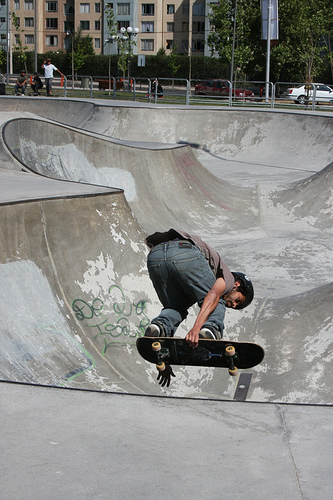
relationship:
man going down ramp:
[143, 225, 255, 340] [0, 382, 332, 500]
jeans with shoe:
[148, 240, 229, 339] [143, 325, 162, 339]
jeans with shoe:
[148, 240, 229, 339] [200, 325, 218, 341]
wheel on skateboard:
[153, 342, 163, 352] [134, 336, 264, 368]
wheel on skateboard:
[226, 345, 236, 357] [134, 336, 264, 368]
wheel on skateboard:
[157, 361, 167, 372] [134, 336, 264, 368]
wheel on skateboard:
[228, 363, 240, 377] [134, 336, 264, 368]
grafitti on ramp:
[72, 286, 151, 352] [0, 111, 250, 400]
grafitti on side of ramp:
[72, 286, 151, 352] [0, 111, 250, 400]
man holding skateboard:
[143, 225, 255, 340] [134, 336, 264, 368]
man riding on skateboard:
[143, 225, 255, 340] [134, 336, 264, 368]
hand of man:
[188, 332, 200, 350] [146, 233, 255, 340]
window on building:
[142, 3, 156, 15] [2, 1, 223, 57]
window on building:
[141, 21, 155, 35] [2, 1, 223, 57]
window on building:
[139, 38, 155, 52] [2, 1, 223, 57]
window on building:
[118, 21, 130, 29] [2, 1, 223, 57]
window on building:
[120, 4, 132, 16] [2, 1, 223, 57]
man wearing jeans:
[146, 233, 255, 340] [148, 240, 229, 339]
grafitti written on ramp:
[72, 286, 151, 352] [0, 111, 250, 400]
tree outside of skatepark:
[278, 1, 332, 88] [1, 94, 332, 478]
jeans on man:
[148, 240, 229, 339] [146, 233, 255, 340]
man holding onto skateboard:
[146, 233, 255, 340] [134, 336, 264, 368]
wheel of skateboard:
[226, 345, 236, 357] [134, 336, 264, 368]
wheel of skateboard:
[228, 363, 240, 377] [134, 336, 264, 368]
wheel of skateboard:
[153, 342, 163, 352] [134, 336, 264, 368]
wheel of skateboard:
[157, 361, 167, 372] [134, 336, 264, 368]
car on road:
[197, 78, 258, 99] [4, 74, 192, 95]